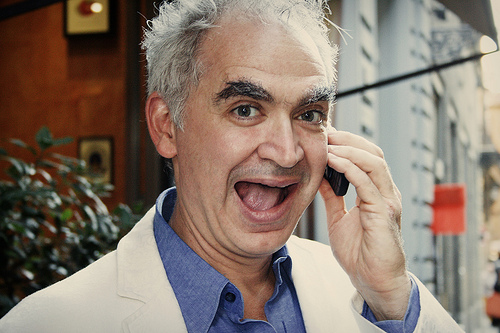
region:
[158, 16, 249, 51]
Man has short hair.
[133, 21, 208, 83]
Man has gray hair.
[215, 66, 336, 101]
Man has dark eye brows.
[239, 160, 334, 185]
Man has gray mustache.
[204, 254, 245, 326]
Man wearing blue shirt.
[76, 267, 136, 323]
Man wearing white jacket.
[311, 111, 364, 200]
Man holding cell phone up to ear.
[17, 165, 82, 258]
Green plant behind man.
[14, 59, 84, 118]
Brown wall behind man.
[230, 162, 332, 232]
Man has mouth open.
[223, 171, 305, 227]
man's mouth is open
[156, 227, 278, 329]
man's shirt is blue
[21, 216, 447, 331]
man's jacket is white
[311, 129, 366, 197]
man is holding a phone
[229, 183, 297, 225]
man's tongue is showing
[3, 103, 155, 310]
green plant behind man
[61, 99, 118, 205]
picture framed on wall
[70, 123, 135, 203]
picture frame is black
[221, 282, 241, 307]
black button on shirt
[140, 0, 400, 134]
man's hair is gray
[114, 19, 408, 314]
happy man holding phone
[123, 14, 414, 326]
happy man talking on the phone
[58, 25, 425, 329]
nicely dressed older gentleman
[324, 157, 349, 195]
small black cellular phone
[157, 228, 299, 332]
collar of a light blue button down shirt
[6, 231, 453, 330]
off-white suit jacket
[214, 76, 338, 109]
man has bushy black eyebrows with flecks of white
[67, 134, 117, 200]
framed art on a wall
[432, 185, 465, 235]
small orange banner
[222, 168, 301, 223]
mouth is open in a happy expression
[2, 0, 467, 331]
man using a phone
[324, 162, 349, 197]
the phone the man is using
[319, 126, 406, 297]
hand holding the phone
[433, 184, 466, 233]
red flag to the right of the man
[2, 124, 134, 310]
green plant behind the man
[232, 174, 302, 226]
open mouth of the man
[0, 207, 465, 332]
white coat man is wearing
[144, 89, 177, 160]
the man's ear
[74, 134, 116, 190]
framed picture on wall by the green plant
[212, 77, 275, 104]
man's eyebrow that's closest to the green plant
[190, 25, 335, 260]
man with surprised expression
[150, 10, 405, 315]
hand holding small cellphone to ear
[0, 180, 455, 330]
blue shirt under white jacket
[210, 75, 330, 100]
bushy dark eyebrows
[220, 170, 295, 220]
tongue inside of mouth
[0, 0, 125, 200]
wood paneling with framed pictures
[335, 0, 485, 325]
gray building with horizontal markings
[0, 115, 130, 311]
plant with dark and glossy leaves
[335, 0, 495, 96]
tip of awning with pole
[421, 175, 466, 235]
orange paper sticking out of building